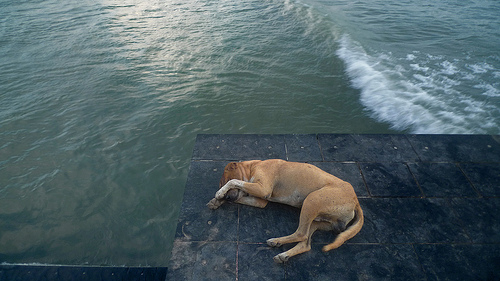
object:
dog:
[205, 159, 364, 263]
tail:
[322, 204, 365, 251]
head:
[219, 160, 252, 204]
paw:
[215, 191, 226, 199]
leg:
[293, 227, 317, 253]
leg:
[280, 188, 324, 243]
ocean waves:
[0, 0, 500, 268]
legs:
[223, 174, 276, 199]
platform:
[165, 128, 498, 281]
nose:
[225, 196, 231, 201]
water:
[4, 6, 495, 266]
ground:
[167, 133, 495, 281]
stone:
[173, 134, 500, 281]